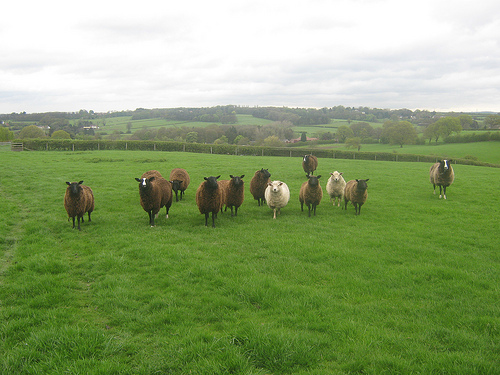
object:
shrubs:
[112, 128, 206, 151]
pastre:
[99, 129, 494, 309]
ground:
[438, 215, 453, 239]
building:
[83, 124, 99, 130]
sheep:
[168, 166, 191, 201]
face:
[135, 177, 155, 188]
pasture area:
[40, 242, 494, 364]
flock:
[131, 152, 371, 227]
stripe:
[142, 177, 147, 187]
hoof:
[165, 214, 168, 218]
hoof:
[150, 223, 156, 228]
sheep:
[299, 152, 319, 178]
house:
[26, 120, 103, 133]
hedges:
[54, 112, 251, 157]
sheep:
[250, 167, 272, 207]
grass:
[0, 152, 500, 375]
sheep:
[265, 180, 291, 220]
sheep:
[216, 173, 245, 217]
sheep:
[194, 175, 226, 228]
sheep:
[134, 170, 172, 228]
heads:
[167, 178, 184, 190]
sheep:
[62, 179, 96, 231]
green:
[368, 255, 464, 287]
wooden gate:
[1, 137, 30, 154]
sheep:
[428, 158, 455, 198]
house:
[285, 135, 318, 143]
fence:
[0, 141, 499, 168]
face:
[204, 174, 221, 187]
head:
[63, 180, 86, 197]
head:
[202, 174, 222, 190]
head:
[229, 174, 245, 185]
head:
[168, 179, 185, 192]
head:
[306, 174, 321, 185]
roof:
[79, 124, 100, 128]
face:
[65, 179, 84, 195]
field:
[0, 129, 497, 375]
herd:
[61, 150, 455, 232]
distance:
[0, 99, 500, 159]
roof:
[291, 136, 319, 140]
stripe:
[442, 159, 449, 169]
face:
[436, 158, 455, 169]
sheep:
[325, 172, 346, 207]